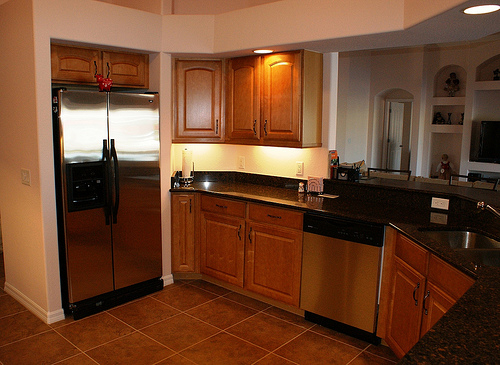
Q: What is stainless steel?
A: Appliances.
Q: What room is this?
A: Kitchen.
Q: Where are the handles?
A: On fridge.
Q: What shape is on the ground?
A: Squares.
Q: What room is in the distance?
A: Living Room.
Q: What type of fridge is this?
A: Side by side.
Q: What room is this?
A: Kitchen.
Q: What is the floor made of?
A: Tile.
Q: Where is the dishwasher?
A: Next to the sink.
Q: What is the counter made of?
A: Black granite.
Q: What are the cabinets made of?
A: Wood.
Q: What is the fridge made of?
A: Stainless steel.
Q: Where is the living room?
A: Behind the sink.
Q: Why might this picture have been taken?
A: To sell the house.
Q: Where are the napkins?
A: Next to the electrical outlet.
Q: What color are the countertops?
A: Black.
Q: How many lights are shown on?
A: Two.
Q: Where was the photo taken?
A: Kitchen.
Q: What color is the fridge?
A: Silver.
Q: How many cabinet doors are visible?
A: Ten.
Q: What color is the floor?
A: Brown.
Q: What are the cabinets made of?
A: Wood.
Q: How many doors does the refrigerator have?
A: Two.